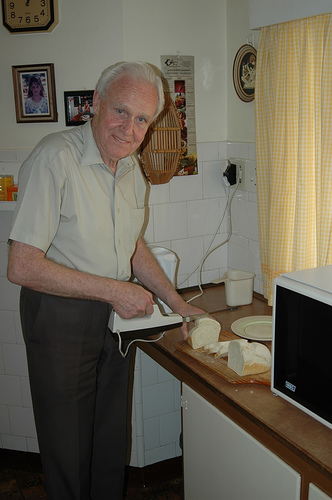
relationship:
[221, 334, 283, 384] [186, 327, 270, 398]
bread on a cutting board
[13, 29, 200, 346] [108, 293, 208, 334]
man holding carving knife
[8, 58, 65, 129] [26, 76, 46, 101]
picture of a girl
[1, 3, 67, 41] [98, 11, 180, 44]
clock on wall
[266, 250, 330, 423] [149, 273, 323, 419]
microwave on counter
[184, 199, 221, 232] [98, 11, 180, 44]
white on wall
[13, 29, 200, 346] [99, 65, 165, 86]
man has white hair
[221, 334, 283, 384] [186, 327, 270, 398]
bread on cutting board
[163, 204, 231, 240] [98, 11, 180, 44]
tiles on wall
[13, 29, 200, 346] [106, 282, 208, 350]
man using a electric slicer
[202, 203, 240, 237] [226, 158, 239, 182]
cords in electrical outlet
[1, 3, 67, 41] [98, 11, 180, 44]
clock behind wall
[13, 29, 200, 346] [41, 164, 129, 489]
gentleman neatley dressed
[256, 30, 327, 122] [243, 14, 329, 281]
curtain over window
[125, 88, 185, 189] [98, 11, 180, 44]
wooden basket on wall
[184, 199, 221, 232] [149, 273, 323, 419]
white door below counter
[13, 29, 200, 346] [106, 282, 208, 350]
man holding carving knife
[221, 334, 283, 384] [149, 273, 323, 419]
bread on counter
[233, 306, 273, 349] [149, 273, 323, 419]
white plate on counter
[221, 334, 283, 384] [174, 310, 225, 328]
bread being sliced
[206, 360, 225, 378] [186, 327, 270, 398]
wood small cutting board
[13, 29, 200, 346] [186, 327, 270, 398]
man using cutting board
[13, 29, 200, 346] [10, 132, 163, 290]
man in shirt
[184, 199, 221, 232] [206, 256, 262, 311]
white plastic cup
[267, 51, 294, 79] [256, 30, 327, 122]
yellow gingham curtain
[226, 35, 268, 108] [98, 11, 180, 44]
plate hung wall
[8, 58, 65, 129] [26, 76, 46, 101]
photo of girl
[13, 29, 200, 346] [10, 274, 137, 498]
man wearing brown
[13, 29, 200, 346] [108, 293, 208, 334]
man using carving knife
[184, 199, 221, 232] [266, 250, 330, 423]
white and black microwave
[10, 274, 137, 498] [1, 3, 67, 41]
brown and tan clock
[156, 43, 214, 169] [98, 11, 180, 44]
poster hanging on wall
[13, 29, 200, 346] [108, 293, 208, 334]
man holds carving knife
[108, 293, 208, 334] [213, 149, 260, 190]
carving knife in electrical outlet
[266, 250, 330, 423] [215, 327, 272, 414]
microwave on a table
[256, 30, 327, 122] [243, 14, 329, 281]
curtain covers window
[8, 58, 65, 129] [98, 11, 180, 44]
female hangs on wall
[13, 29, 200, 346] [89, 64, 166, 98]
man has gray hair